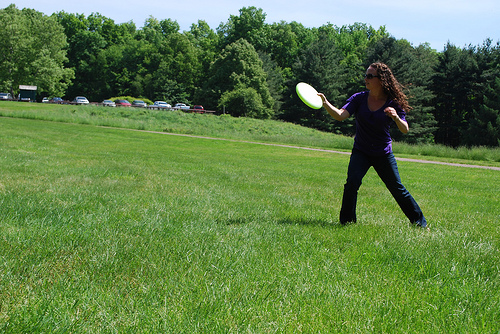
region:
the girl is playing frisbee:
[283, 46, 461, 234]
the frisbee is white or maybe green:
[286, 80, 326, 119]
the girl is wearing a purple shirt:
[347, 78, 417, 155]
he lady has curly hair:
[361, 62, 413, 124]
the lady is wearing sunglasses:
[361, 68, 380, 84]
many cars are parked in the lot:
[49, 95, 210, 117]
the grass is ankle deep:
[126, 180, 301, 317]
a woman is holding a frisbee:
[292, 59, 434, 233]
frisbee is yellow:
[292, 80, 324, 111]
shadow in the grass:
[207, 208, 349, 233]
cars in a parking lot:
[3, 83, 215, 117]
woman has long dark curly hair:
[315, 58, 430, 230]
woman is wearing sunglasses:
[359, 60, 396, 100]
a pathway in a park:
[3, 110, 495, 179]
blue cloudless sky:
[3, 2, 498, 52]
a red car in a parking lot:
[111, 96, 130, 108]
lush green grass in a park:
[2, 112, 499, 332]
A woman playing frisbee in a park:
[290, 52, 433, 239]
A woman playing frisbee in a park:
[290, 60, 431, 231]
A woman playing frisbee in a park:
[295, 58, 431, 234]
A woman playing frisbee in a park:
[291, 55, 437, 233]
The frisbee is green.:
[290, 70, 323, 118]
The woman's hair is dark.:
[368, 58, 416, 115]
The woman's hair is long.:
[360, 53, 413, 112]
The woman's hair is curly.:
[366, 55, 415, 111]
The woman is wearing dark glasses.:
[356, 70, 380, 88]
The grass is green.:
[36, 175, 173, 282]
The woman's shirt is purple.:
[343, 90, 403, 150]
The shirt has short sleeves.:
[338, 88, 366, 126]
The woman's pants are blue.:
[331, 141, 445, 246]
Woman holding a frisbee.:
[294, 79, 324, 111]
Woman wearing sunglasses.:
[361, 70, 377, 80]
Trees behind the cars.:
[0, 1, 217, 110]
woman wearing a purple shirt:
[338, 90, 408, 149]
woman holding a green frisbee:
[288, 75, 325, 114]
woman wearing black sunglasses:
[360, 70, 380, 80]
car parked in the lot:
[72, 90, 87, 107]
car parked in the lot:
[95, 95, 116, 108]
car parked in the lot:
[115, 95, 131, 107]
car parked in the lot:
[156, 93, 171, 109]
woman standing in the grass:
[292, 47, 442, 239]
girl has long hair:
[342, 56, 447, 143]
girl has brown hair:
[368, 55, 425, 121]